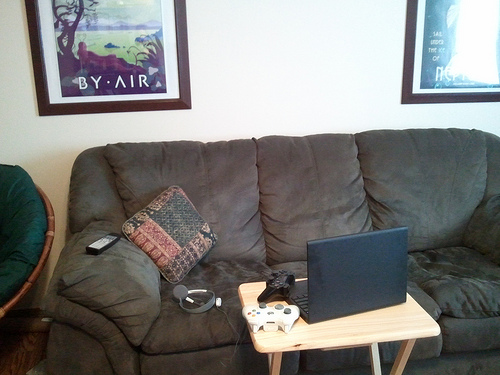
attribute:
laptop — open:
[282, 239, 406, 318]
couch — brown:
[74, 150, 487, 280]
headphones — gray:
[168, 285, 230, 319]